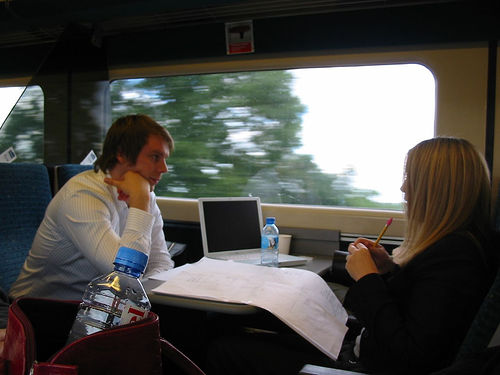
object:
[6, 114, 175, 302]
man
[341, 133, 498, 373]
woman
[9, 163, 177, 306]
shirt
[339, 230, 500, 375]
shirt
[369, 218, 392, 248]
pencil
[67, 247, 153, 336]
water bottle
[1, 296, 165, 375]
bag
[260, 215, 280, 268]
water bottle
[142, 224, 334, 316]
table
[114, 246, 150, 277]
top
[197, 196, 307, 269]
laptop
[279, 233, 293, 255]
paper cup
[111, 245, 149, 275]
cap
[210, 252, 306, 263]
keyboard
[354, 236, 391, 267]
right hand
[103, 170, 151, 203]
right hand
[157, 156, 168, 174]
nose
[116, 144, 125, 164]
ear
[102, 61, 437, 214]
window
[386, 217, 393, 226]
eraser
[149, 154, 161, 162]
eye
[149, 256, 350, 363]
paper